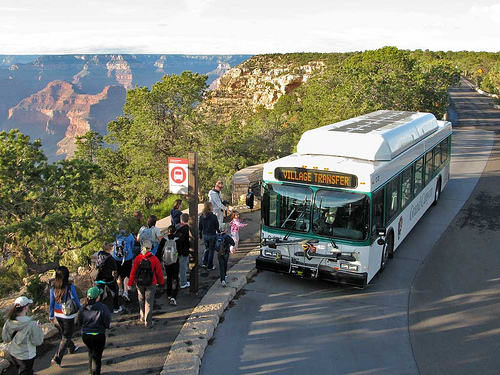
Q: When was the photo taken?
A: Afternoon.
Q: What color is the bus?
A: White.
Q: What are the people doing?
A: Walking.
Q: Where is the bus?
A: On the road.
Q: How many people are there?
A: More than five.